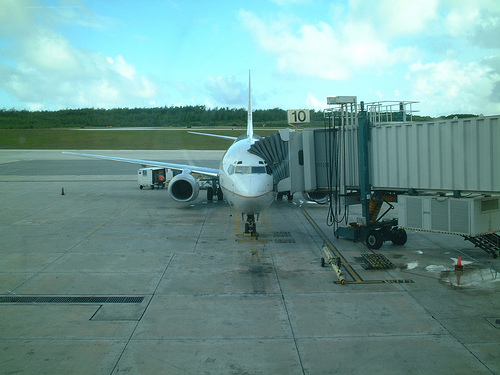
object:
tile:
[280, 286, 452, 338]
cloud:
[6, 7, 160, 107]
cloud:
[197, 67, 270, 115]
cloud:
[238, 10, 383, 82]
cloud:
[410, 59, 494, 95]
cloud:
[445, 7, 499, 43]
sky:
[0, 4, 499, 118]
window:
[227, 161, 274, 179]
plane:
[61, 69, 280, 247]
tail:
[247, 70, 252, 144]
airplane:
[57, 69, 300, 238]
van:
[124, 153, 227, 206]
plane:
[135, 103, 368, 222]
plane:
[61, 65, 303, 245]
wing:
[60, 145, 220, 177]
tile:
[88, 202, 328, 373]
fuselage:
[298, 179, 348, 213]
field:
[46, 127, 188, 154]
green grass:
[62, 134, 97, 147]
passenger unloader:
[253, 112, 498, 257]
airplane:
[33, 67, 339, 244]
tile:
[7, 166, 497, 373]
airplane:
[60, 68, 333, 238]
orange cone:
[453, 254, 464, 275]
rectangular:
[93, 98, 203, 238]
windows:
[230, 165, 272, 178]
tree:
[4, 108, 18, 128]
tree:
[52, 112, 62, 126]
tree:
[165, 110, 180, 121]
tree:
[219, 113, 226, 130]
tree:
[225, 107, 237, 128]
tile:
[4, 283, 158, 335]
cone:
[450, 250, 463, 266]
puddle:
[435, 262, 499, 295]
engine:
[167, 172, 199, 199]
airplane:
[74, 70, 295, 238]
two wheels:
[365, 228, 406, 249]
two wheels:
[202, 185, 221, 202]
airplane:
[58, 57, 363, 284]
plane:
[63, 70, 296, 230]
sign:
[286, 106, 312, 126]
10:
[292, 108, 305, 120]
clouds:
[395, 9, 465, 81]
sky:
[70, 22, 240, 96]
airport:
[0, 98, 499, 373]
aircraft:
[113, 122, 413, 290]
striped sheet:
[56, 182, 73, 204]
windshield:
[227, 164, 270, 177]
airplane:
[60, 67, 283, 238]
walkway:
[274, 117, 498, 203]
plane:
[58, 62, 328, 245]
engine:
[165, 161, 208, 209]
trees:
[1, 105, 496, 130]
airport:
[0, 127, 496, 373]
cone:
[50, 152, 86, 229]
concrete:
[37, 192, 226, 369]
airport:
[42, 45, 439, 366]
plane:
[82, 84, 366, 295]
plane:
[71, 110, 371, 264]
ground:
[19, 119, 482, 356]